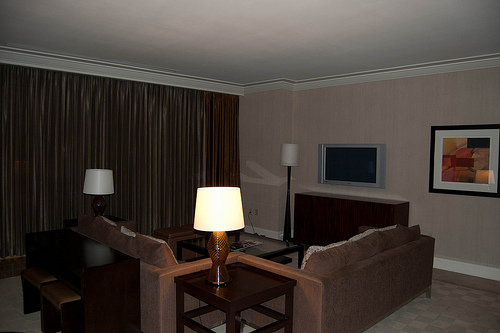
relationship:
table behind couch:
[24, 225, 141, 330] [75, 218, 244, 331]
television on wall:
[316, 139, 387, 188] [305, 90, 420, 128]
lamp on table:
[192, 186, 244, 233] [172, 266, 309, 328]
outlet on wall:
[249, 208, 253, 214] [236, 90, 281, 237]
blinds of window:
[0, 62, 241, 257] [23, 69, 256, 245]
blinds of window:
[0, 62, 241, 257] [6, 62, 272, 250]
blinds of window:
[0, 62, 241, 257] [1, 63, 240, 255]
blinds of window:
[34, 58, 241, 253] [9, 57, 259, 278]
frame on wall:
[415, 113, 497, 220] [227, 55, 499, 286]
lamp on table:
[175, 175, 252, 288] [188, 259, 310, 331]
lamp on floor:
[277, 135, 299, 167] [425, 268, 497, 328]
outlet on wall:
[246, 205, 254, 216] [246, 168, 278, 229]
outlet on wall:
[249, 208, 253, 214] [236, 90, 495, 260]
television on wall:
[316, 139, 387, 188] [248, 101, 489, 272]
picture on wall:
[426, 122, 498, 200] [249, 54, 496, 280]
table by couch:
[173, 259, 297, 331] [237, 221, 437, 328]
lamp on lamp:
[277, 142, 300, 167] [275, 133, 295, 246]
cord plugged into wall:
[248, 211, 257, 218] [248, 89, 283, 220]